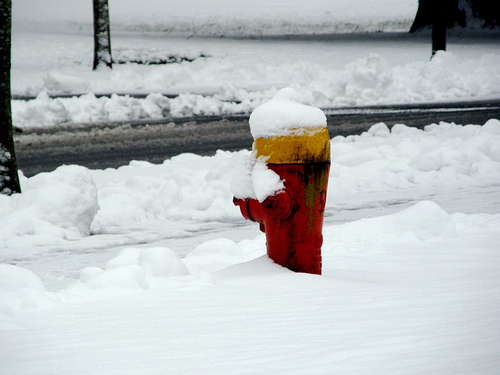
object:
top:
[250, 124, 335, 165]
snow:
[0, 90, 257, 201]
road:
[1, 100, 499, 176]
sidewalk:
[0, 90, 500, 128]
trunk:
[90, 0, 117, 73]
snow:
[96, 28, 110, 61]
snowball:
[29, 160, 103, 238]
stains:
[301, 161, 313, 176]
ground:
[0, 0, 499, 374]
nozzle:
[259, 179, 300, 227]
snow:
[0, 230, 499, 371]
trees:
[0, 0, 22, 195]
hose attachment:
[228, 177, 295, 226]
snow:
[243, 89, 325, 136]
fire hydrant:
[230, 107, 332, 278]